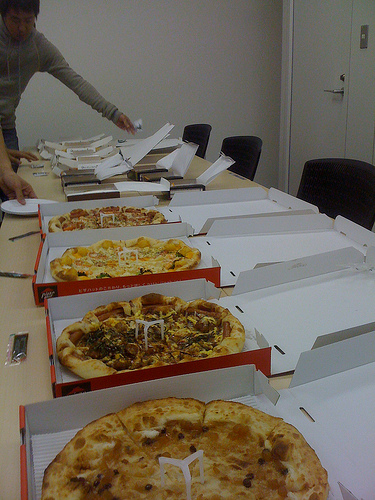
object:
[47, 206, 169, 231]
pizza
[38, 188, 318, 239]
box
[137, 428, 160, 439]
cheese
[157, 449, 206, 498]
object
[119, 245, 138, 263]
object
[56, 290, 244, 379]
pizza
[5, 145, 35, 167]
hand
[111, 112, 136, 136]
hand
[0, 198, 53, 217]
plate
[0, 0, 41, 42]
head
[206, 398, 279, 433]
crust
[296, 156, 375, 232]
chair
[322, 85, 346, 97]
handle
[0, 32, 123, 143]
shirt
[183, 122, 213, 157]
chair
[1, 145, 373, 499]
table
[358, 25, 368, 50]
switchplate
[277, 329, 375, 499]
lid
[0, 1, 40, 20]
hair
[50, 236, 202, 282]
pizza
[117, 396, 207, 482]
pizza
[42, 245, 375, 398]
box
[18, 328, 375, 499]
box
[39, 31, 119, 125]
arm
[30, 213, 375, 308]
box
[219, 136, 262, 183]
chair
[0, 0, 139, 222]
man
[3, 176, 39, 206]
hand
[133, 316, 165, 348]
toppings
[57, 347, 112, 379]
crust